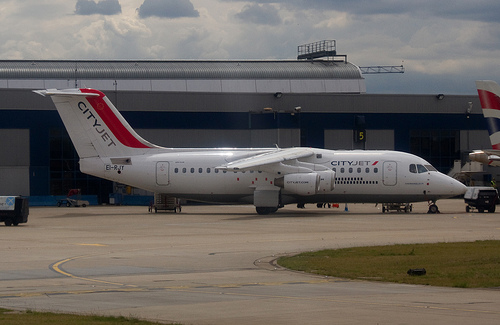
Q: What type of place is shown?
A: It is an airport.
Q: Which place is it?
A: It is an airport.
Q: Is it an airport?
A: Yes, it is an airport.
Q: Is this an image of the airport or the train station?
A: It is showing the airport.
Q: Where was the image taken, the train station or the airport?
A: It was taken at the airport.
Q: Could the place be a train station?
A: No, it is an airport.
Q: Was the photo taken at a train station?
A: No, the picture was taken in an airport.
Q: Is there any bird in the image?
A: No, there are no birds.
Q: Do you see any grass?
A: Yes, there is grass.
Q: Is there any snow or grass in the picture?
A: Yes, there is grass.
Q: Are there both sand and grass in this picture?
A: No, there is grass but no sand.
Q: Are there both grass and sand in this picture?
A: No, there is grass but no sand.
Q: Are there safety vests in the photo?
A: No, there are no safety vests.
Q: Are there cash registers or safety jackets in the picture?
A: No, there are no safety jackets or cash registers.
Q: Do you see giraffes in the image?
A: No, there are no giraffes.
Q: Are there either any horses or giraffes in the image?
A: No, there are no giraffes or horses.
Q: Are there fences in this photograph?
A: No, there are no fences.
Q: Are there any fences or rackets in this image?
A: No, there are no fences or rackets.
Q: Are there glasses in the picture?
A: No, there are no glasses.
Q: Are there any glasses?
A: No, there are no glasses.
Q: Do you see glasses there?
A: No, there are no glasses.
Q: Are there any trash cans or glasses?
A: No, there are no glasses or trash cans.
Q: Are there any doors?
A: Yes, there is a door.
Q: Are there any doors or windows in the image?
A: Yes, there is a door.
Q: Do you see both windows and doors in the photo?
A: Yes, there are both a door and windows.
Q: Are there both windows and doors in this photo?
A: Yes, there are both a door and windows.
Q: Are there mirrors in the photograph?
A: No, there are no mirrors.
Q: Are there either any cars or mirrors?
A: No, there are no mirrors or cars.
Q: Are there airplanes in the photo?
A: Yes, there is an airplane.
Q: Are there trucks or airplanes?
A: Yes, there is an airplane.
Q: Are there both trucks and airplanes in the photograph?
A: No, there is an airplane but no trucks.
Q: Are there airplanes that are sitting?
A: Yes, there is an airplane that is sitting.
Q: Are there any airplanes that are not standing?
A: Yes, there is an airplane that is sitting.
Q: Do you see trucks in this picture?
A: No, there are no trucks.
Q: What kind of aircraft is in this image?
A: The aircraft is an airplane.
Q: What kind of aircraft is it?
A: The aircraft is an airplane.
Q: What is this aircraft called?
A: This is an airplane.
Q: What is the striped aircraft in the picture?
A: The aircraft is an airplane.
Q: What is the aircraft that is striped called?
A: The aircraft is an airplane.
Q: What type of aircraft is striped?
A: The aircraft is an airplane.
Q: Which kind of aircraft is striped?
A: The aircraft is an airplane.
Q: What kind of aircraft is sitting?
A: The aircraft is an airplane.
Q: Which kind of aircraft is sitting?
A: The aircraft is an airplane.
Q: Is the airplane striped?
A: Yes, the airplane is striped.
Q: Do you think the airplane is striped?
A: Yes, the airplane is striped.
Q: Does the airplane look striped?
A: Yes, the airplane is striped.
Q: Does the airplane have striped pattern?
A: Yes, the airplane is striped.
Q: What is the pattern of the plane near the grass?
A: The plane is striped.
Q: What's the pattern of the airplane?
A: The plane is striped.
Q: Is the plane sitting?
A: Yes, the plane is sitting.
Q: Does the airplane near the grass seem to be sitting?
A: Yes, the plane is sitting.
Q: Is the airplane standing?
A: No, the airplane is sitting.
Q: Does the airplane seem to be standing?
A: No, the airplane is sitting.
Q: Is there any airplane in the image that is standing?
A: No, there is an airplane but it is sitting.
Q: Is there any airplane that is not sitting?
A: No, there is an airplane but it is sitting.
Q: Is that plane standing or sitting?
A: The plane is sitting.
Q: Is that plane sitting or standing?
A: The plane is sitting.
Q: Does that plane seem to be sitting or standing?
A: The plane is sitting.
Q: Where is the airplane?
A: The airplane is at the airport.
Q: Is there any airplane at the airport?
A: Yes, there is an airplane at the airport.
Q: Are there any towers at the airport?
A: No, there is an airplane at the airport.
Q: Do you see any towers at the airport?
A: No, there is an airplane at the airport.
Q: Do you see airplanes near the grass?
A: Yes, there is an airplane near the grass.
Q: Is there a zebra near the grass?
A: No, there is an airplane near the grass.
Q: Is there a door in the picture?
A: Yes, there is a door.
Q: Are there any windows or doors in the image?
A: Yes, there is a door.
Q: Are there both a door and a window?
A: Yes, there are both a door and a window.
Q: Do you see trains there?
A: No, there are no trains.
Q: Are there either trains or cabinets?
A: No, there are no trains or cabinets.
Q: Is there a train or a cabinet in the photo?
A: No, there are no trains or cabinets.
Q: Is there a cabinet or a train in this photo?
A: No, there are no trains or cabinets.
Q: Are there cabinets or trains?
A: No, there are no trains or cabinets.